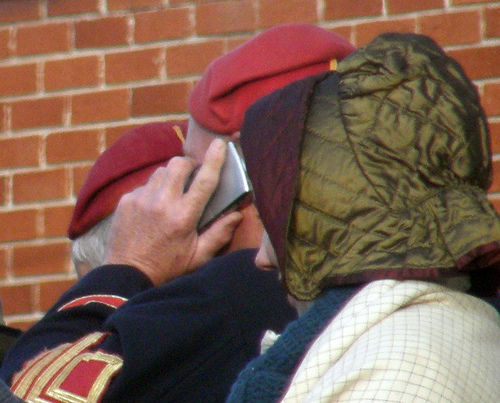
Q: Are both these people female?
A: No, they are both male and female.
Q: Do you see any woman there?
A: Yes, there is a woman.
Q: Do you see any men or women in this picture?
A: Yes, there is a woman.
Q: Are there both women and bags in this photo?
A: No, there is a woman but no bags.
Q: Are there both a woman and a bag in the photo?
A: No, there is a woman but no bags.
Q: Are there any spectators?
A: No, there are no spectators.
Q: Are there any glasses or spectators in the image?
A: No, there are no spectators or glasses.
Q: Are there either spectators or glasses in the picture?
A: No, there are no spectators or glasses.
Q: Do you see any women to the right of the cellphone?
A: Yes, there is a woman to the right of the cellphone.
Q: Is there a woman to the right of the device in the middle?
A: Yes, there is a woman to the right of the cellphone.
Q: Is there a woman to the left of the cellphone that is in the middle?
A: No, the woman is to the right of the mobile phone.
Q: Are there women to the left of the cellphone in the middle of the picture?
A: No, the woman is to the right of the mobile phone.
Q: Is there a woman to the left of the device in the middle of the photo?
A: No, the woman is to the right of the mobile phone.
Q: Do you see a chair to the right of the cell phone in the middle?
A: No, there is a woman to the right of the cell phone.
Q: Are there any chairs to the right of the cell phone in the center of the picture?
A: No, there is a woman to the right of the cell phone.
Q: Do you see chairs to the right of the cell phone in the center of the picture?
A: No, there is a woman to the right of the cell phone.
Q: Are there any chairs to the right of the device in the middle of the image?
A: No, there is a woman to the right of the cell phone.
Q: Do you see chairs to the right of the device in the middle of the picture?
A: No, there is a woman to the right of the cell phone.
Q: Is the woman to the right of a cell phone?
A: Yes, the woman is to the right of a cell phone.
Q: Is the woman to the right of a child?
A: No, the woman is to the right of a cell phone.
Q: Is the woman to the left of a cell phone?
A: No, the woman is to the right of a cell phone.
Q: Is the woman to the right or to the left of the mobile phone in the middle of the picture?
A: The woman is to the right of the cell phone.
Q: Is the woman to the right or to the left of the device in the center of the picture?
A: The woman is to the right of the cell phone.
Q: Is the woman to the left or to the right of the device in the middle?
A: The woman is to the right of the cell phone.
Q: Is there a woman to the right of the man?
A: Yes, there is a woman to the right of the man.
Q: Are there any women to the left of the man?
A: No, the woman is to the right of the man.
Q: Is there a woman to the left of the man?
A: No, the woman is to the right of the man.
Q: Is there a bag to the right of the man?
A: No, there is a woman to the right of the man.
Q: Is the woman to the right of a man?
A: Yes, the woman is to the right of a man.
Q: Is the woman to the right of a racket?
A: No, the woman is to the right of a man.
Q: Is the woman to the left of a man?
A: No, the woman is to the right of a man.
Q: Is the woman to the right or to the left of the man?
A: The woman is to the right of the man.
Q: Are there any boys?
A: No, there are no boys.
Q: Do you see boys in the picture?
A: No, there are no boys.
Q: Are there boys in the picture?
A: No, there are no boys.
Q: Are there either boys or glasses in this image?
A: No, there are no boys or glasses.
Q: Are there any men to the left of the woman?
A: Yes, there is a man to the left of the woman.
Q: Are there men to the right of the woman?
A: No, the man is to the left of the woman.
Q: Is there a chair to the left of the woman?
A: No, there is a man to the left of the woman.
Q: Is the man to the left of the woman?
A: Yes, the man is to the left of the woman.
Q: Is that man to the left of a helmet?
A: No, the man is to the left of the woman.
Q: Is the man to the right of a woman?
A: No, the man is to the left of a woman.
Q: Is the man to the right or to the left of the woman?
A: The man is to the left of the woman.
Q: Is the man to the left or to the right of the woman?
A: The man is to the left of the woman.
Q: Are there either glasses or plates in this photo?
A: No, there are no plates or glasses.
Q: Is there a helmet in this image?
A: No, there are no helmets.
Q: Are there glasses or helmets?
A: No, there are no helmets or glasses.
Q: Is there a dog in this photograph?
A: No, there are no dogs.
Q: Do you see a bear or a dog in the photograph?
A: No, there are no dogs or bears.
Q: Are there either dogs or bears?
A: No, there are no dogs or bears.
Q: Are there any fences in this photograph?
A: No, there are no fences.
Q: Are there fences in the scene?
A: No, there are no fences.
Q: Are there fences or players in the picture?
A: No, there are no fences or players.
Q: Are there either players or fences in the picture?
A: No, there are no fences or players.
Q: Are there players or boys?
A: No, there are no boys or players.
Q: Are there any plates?
A: No, there are no plates.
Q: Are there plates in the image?
A: No, there are no plates.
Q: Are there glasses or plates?
A: No, there are no plates or glasses.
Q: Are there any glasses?
A: No, there are no glasses.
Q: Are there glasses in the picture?
A: No, there are no glasses.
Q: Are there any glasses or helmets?
A: No, there are no glasses or helmets.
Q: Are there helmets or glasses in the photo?
A: No, there are no glasses or helmets.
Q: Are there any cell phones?
A: Yes, there is a cell phone.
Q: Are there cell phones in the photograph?
A: Yes, there is a cell phone.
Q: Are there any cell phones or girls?
A: Yes, there is a cell phone.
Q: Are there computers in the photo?
A: No, there are no computers.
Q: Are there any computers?
A: No, there are no computers.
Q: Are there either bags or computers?
A: No, there are no computers or bags.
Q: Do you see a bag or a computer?
A: No, there are no computers or bags.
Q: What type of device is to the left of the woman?
A: The device is a cell phone.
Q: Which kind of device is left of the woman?
A: The device is a cell phone.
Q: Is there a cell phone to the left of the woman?
A: Yes, there is a cell phone to the left of the woman.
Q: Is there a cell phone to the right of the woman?
A: No, the cell phone is to the left of the woman.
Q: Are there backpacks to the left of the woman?
A: No, there is a cell phone to the left of the woman.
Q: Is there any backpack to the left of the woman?
A: No, there is a cell phone to the left of the woman.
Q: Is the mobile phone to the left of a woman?
A: Yes, the mobile phone is to the left of a woman.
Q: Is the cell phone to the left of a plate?
A: No, the cell phone is to the left of a woman.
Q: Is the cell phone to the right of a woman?
A: No, the cell phone is to the left of a woman.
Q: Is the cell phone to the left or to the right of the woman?
A: The cell phone is to the left of the woman.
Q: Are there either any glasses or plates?
A: No, there are no glasses or plates.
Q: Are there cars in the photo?
A: No, there are no cars.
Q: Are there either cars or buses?
A: No, there are no cars or buses.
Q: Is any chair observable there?
A: No, there are no chairs.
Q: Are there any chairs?
A: No, there are no chairs.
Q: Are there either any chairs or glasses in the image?
A: No, there are no chairs or glasses.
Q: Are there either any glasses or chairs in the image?
A: No, there are no chairs or glasses.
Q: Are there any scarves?
A: Yes, there is a scarf.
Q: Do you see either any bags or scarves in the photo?
A: Yes, there is a scarf.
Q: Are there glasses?
A: No, there are no glasses.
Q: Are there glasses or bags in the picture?
A: No, there are no glasses or bags.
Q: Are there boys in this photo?
A: No, there are no boys.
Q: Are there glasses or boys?
A: No, there are no boys or glasses.